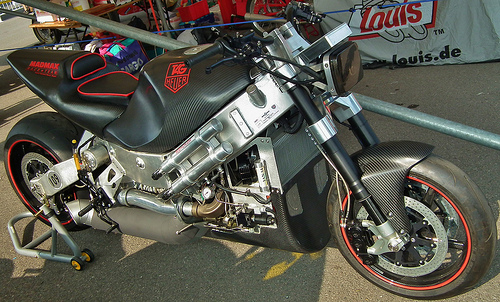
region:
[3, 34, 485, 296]
A motorcycle sitting outside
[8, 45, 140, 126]
Seat on motorcycle is black and red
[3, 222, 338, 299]
Shadow of the motorcycle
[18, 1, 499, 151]
A slanted silver pole behind the motorcycle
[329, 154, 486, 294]
A wheel on the motorcycle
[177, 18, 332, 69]
Black handles on the motorcycle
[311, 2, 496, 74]
A cloth with words on it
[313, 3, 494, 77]
the cloth is big and white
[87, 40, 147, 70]
Bags near the motorcycle outside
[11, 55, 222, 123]
Words are on the motorcycle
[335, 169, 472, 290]
narrow red stripe on front tire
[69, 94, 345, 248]
silver engine of a black motorcycle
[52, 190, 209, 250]
silver exhaust pipe of a motorcycle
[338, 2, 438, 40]
white sign with red lettering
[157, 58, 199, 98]
red lettering on a black motorcycle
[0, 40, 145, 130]
red letters and trim on a black motorcycle seat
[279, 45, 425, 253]
black and silver front spokes of a motorcycle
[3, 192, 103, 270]
wheeled gray stand for motorcycle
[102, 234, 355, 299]
dark shadows on pavement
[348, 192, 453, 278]
disc brake on motorcycle wheel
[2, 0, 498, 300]
One parked motorcycle.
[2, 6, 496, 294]
motorcycle parked on the street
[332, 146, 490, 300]
red and white tire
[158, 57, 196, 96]
red design on the black motorbike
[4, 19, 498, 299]
red, black, and silver bike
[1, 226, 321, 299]
shadows on the ground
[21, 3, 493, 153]
silver pole running alongside the bike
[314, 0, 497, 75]
crinkled banner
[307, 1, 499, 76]
red, white, and black banner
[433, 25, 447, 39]
small black trademark symbol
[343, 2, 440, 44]
red, white, and black logo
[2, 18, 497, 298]
black and silver motorcycle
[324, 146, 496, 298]
front wheel with red rim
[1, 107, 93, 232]
rear wheel with red rim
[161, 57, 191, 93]
red emblem on motorcycle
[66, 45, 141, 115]
seat with red trim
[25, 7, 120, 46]
part of picnic table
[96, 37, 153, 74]
purple and pink bag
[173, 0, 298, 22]
red objects in background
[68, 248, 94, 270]
little yellow and black wheels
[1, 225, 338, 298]
shadow of motorcycle